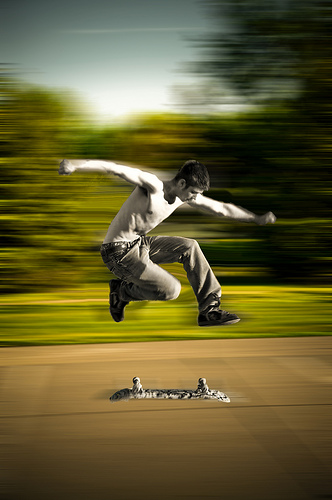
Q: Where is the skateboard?
A: Under the man.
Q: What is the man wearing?
A: Jeans.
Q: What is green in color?
A: Trees.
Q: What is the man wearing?
A: Jeans.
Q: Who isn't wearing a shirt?
A: The man.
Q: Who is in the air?
A: The man.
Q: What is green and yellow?
A: Scenery.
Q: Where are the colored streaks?
A: Across grass and trees.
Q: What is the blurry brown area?
A: Dirt.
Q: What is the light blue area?
A: Sky.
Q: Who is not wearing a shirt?
A: Skateboarder.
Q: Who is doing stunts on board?
A: Skater.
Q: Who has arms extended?
A: Skater.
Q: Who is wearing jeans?
A: Skater.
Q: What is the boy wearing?
A: Jeans.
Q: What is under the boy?
A: Skateboard.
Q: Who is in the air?
A: A young man.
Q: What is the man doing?
A: Riding a skateboard.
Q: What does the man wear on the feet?
A: Shoes.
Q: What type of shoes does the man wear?
A: Sneakers.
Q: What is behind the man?
A: Trees.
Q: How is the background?
A: Blurry.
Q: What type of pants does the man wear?
A: Jeans.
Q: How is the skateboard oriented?
A: Upside down.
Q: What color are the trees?
A: Green.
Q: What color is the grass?
A: Green.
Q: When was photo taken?
A: Daytime.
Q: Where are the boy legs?
A: Up in air.